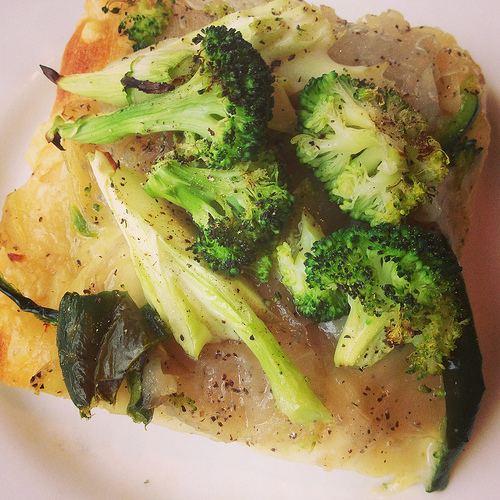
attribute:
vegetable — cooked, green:
[38, 283, 185, 435]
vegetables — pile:
[61, 40, 461, 457]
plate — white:
[4, 9, 489, 494]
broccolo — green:
[295, 219, 466, 405]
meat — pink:
[191, 330, 416, 445]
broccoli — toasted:
[289, 67, 451, 228]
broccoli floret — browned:
[295, 68, 448, 228]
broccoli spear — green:
[65, 26, 277, 167]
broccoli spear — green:
[144, 150, 294, 279]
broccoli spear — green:
[288, 69, 458, 229]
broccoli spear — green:
[302, 220, 469, 375]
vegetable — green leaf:
[53, 26, 273, 163]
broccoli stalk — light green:
[332, 300, 392, 365]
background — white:
[455, 16, 475, 50]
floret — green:
[83, 49, 337, 178]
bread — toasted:
[56, 11, 134, 120]